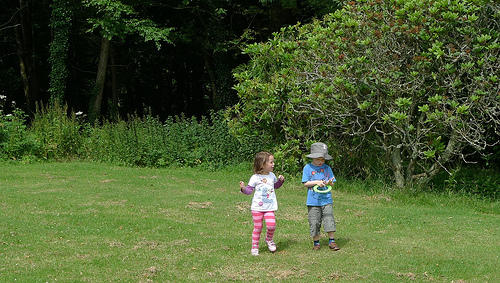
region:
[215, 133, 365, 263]
Two children walking together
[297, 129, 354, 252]
A boy in a hat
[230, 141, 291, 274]
A girl with stripped tights.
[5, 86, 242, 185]
A row of plants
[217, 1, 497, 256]
Children in front of a tree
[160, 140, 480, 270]
Children walking on grass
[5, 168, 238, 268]
A large patch of grass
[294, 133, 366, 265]
A boy holding a green toy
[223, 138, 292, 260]
A girl with long hair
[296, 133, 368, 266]
A boy wearing shorts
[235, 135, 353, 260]
two children playing in the grass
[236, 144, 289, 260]
a small child in pink leggings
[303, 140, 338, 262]
a small child in a fishing hat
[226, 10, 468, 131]
a lush green bush with branches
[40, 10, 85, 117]
a tree trunk covered in green vines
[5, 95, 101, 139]
queen anne's lace and tall grass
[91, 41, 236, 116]
deep dark forest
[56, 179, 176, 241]
green lawn cut short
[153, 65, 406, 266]
two children playing on the lawn near a forest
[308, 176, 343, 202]
a small frisbee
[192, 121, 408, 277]
Two children standing in a backyard.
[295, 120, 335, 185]
The boy is wearing a hat.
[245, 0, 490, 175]
A small tree.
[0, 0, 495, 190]
A forest.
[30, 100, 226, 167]
Tall weeds.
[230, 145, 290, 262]
The girl is wearing striped pants.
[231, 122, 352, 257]
The girl is looking at the boy.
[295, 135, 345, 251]
The boy is holding a green frisbee.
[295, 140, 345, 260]
The boy's t-shirt is blue.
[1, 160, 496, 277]
Small piles of dead grass cover the lawn.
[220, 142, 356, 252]
Two children walking on grass.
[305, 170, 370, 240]
A little boy holding a green Frisbee.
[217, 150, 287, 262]
The little girl is wearing pink-striped stalkings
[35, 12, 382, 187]
A green wooded area in the background.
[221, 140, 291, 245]
A small girl appears to move her arms in a excited manner.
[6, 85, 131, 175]
White flowers appear just outside of the woods.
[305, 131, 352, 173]
The little boy is wearing a grey hat.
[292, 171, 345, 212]
The little has on a blue shirt.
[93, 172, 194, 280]
Grass clippings that have turned brown.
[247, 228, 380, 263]
Both the boy and girl have small shadows beneath them.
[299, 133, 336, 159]
an oversized grey hat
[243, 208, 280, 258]
a pair of pink pants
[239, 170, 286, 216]
a purple and white shirt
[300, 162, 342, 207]
a blue and pink shirt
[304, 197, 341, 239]
a pair of grey cargo pants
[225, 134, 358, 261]
two children walking together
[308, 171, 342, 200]
a green flying disc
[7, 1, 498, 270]
children walking through a field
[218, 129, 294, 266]
a young girl stands on the grass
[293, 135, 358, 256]
a young boy stands on the grass